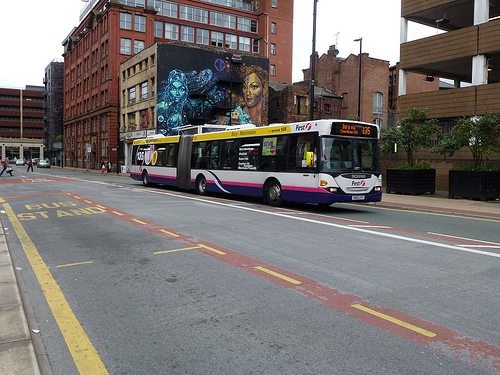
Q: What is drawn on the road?
A: Lines.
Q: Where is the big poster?
A: On the building.